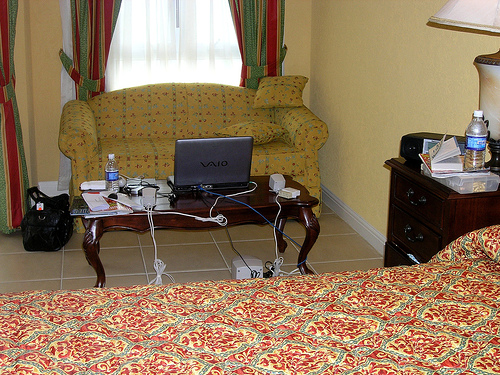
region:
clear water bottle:
[97, 148, 121, 185]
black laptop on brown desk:
[161, 128, 265, 195]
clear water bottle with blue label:
[465, 99, 490, 159]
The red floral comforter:
[0, 227, 498, 371]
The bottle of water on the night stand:
[464, 105, 493, 170]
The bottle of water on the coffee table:
[98, 150, 128, 189]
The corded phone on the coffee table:
[137, 182, 178, 287]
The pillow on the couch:
[217, 75, 309, 140]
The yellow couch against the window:
[67, 0, 284, 96]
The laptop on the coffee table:
[153, 132, 267, 196]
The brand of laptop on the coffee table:
[192, 157, 237, 172]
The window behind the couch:
[84, 0, 251, 85]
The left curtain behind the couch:
[58, 2, 127, 92]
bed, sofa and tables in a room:
[5, 9, 491, 369]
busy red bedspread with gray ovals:
[10, 226, 494, 369]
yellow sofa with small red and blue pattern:
[57, 77, 329, 224]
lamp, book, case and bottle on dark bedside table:
[381, 5, 493, 275]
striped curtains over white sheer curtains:
[56, 3, 289, 104]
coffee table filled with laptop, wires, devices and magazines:
[74, 135, 320, 280]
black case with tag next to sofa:
[16, 97, 83, 254]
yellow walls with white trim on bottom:
[4, 3, 496, 257]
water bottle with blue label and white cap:
[463, 106, 487, 173]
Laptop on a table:
[166, 138, 261, 194]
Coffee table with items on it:
[61, 165, 323, 277]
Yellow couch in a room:
[60, 73, 344, 233]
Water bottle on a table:
[101, 145, 126, 195]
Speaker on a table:
[264, 165, 302, 212]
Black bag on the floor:
[18, 180, 78, 255]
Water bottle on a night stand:
[467, 110, 484, 170]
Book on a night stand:
[417, 132, 464, 180]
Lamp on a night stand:
[425, 3, 498, 148]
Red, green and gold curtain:
[60, 0, 127, 92]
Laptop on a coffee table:
[165, 135, 257, 195]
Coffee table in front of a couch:
[67, 171, 319, 286]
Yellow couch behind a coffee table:
[56, 80, 330, 220]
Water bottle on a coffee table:
[102, 151, 122, 196]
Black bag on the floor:
[20, 184, 75, 254]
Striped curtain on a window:
[225, 0, 286, 90]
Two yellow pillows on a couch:
[219, 72, 309, 146]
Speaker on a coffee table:
[266, 170, 288, 199]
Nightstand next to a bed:
[379, 155, 499, 282]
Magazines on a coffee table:
[67, 187, 133, 223]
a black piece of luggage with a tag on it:
[20, 184, 75, 254]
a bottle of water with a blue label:
[463, 110, 487, 173]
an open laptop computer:
[165, 137, 255, 194]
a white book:
[429, 133, 464, 173]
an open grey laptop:
[166, 135, 256, 196]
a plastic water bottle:
[464, 110, 489, 179]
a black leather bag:
[20, 184, 70, 254]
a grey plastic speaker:
[266, 173, 288, 193]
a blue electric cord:
[201, 183, 308, 260]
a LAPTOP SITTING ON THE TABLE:
[121, 128, 305, 258]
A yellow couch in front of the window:
[11, 83, 366, 185]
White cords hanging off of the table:
[126, 179, 186, 303]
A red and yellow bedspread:
[208, 325, 415, 357]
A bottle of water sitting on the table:
[86, 136, 136, 216]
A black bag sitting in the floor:
[10, 173, 77, 259]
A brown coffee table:
[58, 183, 319, 304]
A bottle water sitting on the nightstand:
[448, 136, 495, 181]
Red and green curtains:
[59, 20, 131, 87]